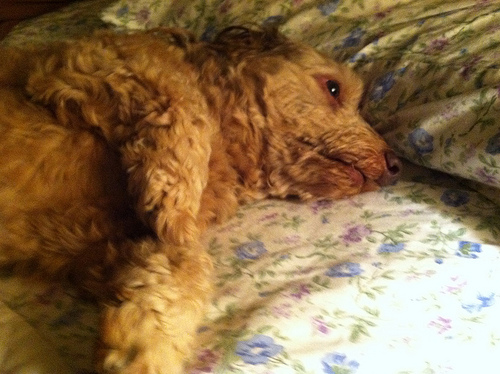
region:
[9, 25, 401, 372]
Dog laying on the bed.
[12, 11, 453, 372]
Brown dog laying on a bed with eyes open.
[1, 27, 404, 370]
Brown dog with curly hair.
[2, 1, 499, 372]
Dog laying on floral linen.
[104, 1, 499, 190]
Pillow with floral pillow case.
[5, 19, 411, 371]
Dog laying on floral sheet.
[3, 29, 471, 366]
Dog laying on its side on the bed.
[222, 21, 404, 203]
Dog's eyes open while laying on the bed.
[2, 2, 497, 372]
Dog resting on floral sheets on the bed.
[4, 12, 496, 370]
Dog waking up from a nap on the bed.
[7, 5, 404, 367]
Brown dog lying on bed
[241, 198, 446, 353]
Blue flower comforter on bed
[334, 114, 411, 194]
Dog nose near pillow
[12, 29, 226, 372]
Dog legs of a brown dog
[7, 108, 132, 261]
Brown fur on a dog's belly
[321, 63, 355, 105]
Black dog eye of a brown dog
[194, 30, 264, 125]
Furry brown dog ear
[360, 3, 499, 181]
Pillow on a bed under blanket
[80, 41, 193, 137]
Brown dog fur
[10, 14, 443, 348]
Big brown dog lying on a bed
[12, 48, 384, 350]
one dog is seen.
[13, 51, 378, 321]
dog is lying down.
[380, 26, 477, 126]
one pillow is seen.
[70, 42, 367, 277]
dog is lying in cot.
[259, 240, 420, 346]
bedspread has floral prints in it.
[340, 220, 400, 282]
flowers are blue and purple in color.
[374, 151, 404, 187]
dog nose is black color.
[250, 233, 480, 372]
light reflection is seen in bedspread.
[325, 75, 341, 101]
eyes is black color.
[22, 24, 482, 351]
dog is lying down with legs folded.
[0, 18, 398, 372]
A brown dog lying down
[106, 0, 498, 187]
The dog's head on a floral pillow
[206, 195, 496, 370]
Part of a floral sheet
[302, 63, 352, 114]
The dog's eye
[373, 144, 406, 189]
The dog's brown nose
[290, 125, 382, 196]
The dog's mouth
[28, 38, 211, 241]
The dog's leg against its body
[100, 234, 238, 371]
The dog's leg on the floral sheet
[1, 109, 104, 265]
The dog's belly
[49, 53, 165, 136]
The dog's wavy brown fur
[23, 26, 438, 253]
dog laying in bed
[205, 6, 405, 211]
top of head on pillow edge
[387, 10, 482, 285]
floral pattern on pillowcase and sheets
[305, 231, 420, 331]
blue flowers with green leaves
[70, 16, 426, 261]
dog laying on side of body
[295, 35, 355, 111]
white dot on glassy dark eye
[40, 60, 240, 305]
one paw on top of leg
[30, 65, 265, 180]
dog with curled light-brown fur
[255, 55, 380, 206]
darker fur around mouth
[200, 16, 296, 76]
dark fur on back of head